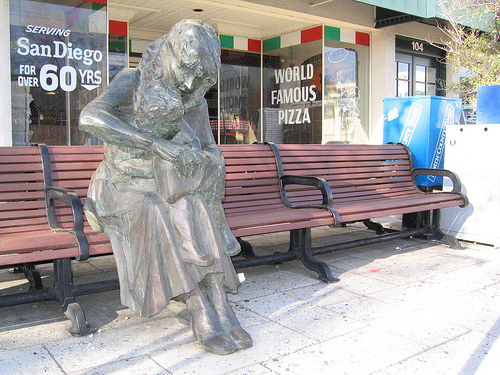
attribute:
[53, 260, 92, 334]
leg — black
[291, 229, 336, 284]
leg — black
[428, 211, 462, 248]
leg — black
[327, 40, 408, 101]
door — black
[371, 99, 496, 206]
dispenser — newspaper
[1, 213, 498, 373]
sidewalk — grey, tile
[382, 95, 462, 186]
holder — blue, white, newspaper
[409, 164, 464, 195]
armrests — black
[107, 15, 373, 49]
sign — red, white, Green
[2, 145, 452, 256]
benches — brown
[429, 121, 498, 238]
box — white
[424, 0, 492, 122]
tree — green